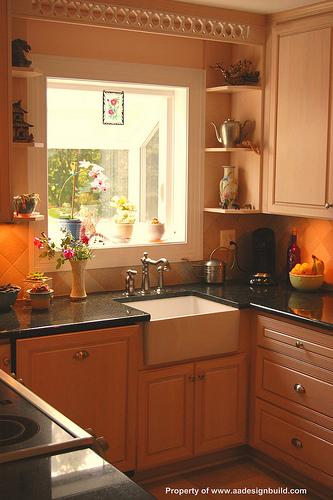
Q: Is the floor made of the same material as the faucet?
A: No, the floor is made of wood and the faucet is made of metal.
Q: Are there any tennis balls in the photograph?
A: No, there are no tennis balls.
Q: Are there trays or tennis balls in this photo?
A: No, there are no tennis balls or trays.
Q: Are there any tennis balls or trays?
A: No, there are no tennis balls or trays.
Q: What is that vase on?
A: The vase is on the shelf.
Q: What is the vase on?
A: The vase is on the shelf.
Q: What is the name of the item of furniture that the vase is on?
A: The piece of furniture is a shelf.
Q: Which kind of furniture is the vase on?
A: The vase is on the shelf.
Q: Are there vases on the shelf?
A: Yes, there is a vase on the shelf.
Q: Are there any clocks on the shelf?
A: No, there is a vase on the shelf.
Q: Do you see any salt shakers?
A: No, there are no salt shakers.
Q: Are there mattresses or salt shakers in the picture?
A: No, there are no salt shakers or mattresses.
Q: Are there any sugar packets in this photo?
A: No, there are no sugar packets.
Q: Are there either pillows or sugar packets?
A: No, there are no sugar packets or pillows.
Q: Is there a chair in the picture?
A: No, there are no chairs.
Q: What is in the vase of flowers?
A: The flowers are in the vase.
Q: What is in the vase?
A: The flowers are in the vase.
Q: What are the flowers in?
A: The flowers are in the vase.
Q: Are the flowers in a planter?
A: No, the flowers are in a vase.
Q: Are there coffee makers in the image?
A: Yes, there is a coffee maker.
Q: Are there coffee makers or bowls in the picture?
A: Yes, there is a coffee maker.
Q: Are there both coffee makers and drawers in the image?
A: Yes, there are both a coffee maker and a drawer.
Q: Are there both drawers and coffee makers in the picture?
A: Yes, there are both a coffee maker and a drawer.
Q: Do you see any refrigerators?
A: No, there are no refrigerators.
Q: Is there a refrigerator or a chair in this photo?
A: No, there are no refrigerators or chairs.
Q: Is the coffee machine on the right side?
A: Yes, the coffee machine is on the right of the image.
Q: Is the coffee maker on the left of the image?
A: No, the coffee maker is on the right of the image.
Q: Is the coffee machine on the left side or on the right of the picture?
A: The coffee machine is on the right of the image.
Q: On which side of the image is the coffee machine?
A: The coffee machine is on the right of the image.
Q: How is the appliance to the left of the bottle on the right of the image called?
A: The appliance is a coffee maker.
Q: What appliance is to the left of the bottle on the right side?
A: The appliance is a coffee maker.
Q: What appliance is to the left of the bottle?
A: The appliance is a coffee maker.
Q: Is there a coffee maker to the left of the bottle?
A: Yes, there is a coffee maker to the left of the bottle.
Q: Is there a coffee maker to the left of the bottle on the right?
A: Yes, there is a coffee maker to the left of the bottle.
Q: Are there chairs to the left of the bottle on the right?
A: No, there is a coffee maker to the left of the bottle.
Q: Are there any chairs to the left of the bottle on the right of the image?
A: No, there is a coffee maker to the left of the bottle.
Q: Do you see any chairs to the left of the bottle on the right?
A: No, there is a coffee maker to the left of the bottle.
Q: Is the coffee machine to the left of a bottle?
A: Yes, the coffee machine is to the left of a bottle.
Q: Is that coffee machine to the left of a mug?
A: No, the coffee machine is to the left of a bottle.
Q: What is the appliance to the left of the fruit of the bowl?
A: The appliance is a coffee maker.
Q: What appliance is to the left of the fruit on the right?
A: The appliance is a coffee maker.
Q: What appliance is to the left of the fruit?
A: The appliance is a coffee maker.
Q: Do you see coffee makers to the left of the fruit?
A: Yes, there is a coffee maker to the left of the fruit.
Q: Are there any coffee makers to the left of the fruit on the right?
A: Yes, there is a coffee maker to the left of the fruit.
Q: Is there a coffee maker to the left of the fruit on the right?
A: Yes, there is a coffee maker to the left of the fruit.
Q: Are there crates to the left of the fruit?
A: No, there is a coffee maker to the left of the fruit.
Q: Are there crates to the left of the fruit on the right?
A: No, there is a coffee maker to the left of the fruit.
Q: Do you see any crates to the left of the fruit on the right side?
A: No, there is a coffee maker to the left of the fruit.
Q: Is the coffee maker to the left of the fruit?
A: Yes, the coffee maker is to the left of the fruit.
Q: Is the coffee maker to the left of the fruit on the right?
A: Yes, the coffee maker is to the left of the fruit.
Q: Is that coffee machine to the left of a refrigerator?
A: No, the coffee machine is to the left of the fruit.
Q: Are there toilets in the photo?
A: No, there are no toilets.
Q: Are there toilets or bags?
A: No, there are no toilets or bags.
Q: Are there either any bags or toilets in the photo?
A: No, there are no toilets or bags.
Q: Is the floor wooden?
A: Yes, the floor is wooden.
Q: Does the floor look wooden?
A: Yes, the floor is wooden.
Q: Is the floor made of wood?
A: Yes, the floor is made of wood.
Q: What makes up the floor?
A: The floor is made of wood.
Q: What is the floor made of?
A: The floor is made of wood.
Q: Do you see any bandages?
A: No, there are no bandages.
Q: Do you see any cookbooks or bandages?
A: No, there are no bandages or cookbooks.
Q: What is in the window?
A: The orchid is in the window.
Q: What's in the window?
A: The orchid is in the window.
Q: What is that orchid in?
A: The orchid is in the window.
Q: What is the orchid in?
A: The orchid is in the window.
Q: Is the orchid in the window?
A: Yes, the orchid is in the window.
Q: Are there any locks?
A: No, there are no locks.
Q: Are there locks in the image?
A: No, there are no locks.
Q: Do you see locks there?
A: No, there are no locks.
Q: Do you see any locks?
A: No, there are no locks.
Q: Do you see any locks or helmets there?
A: No, there are no locks or helmets.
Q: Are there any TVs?
A: No, there are no tvs.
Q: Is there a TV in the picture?
A: No, there are no televisions.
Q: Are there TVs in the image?
A: No, there are no tvs.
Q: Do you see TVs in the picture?
A: No, there are no tvs.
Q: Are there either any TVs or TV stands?
A: No, there are no TVs or TV stands.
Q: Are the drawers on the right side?
A: Yes, the drawers are on the right of the image.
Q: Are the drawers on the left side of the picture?
A: No, the drawers are on the right of the image.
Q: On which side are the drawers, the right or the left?
A: The drawers are on the right of the image.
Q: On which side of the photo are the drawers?
A: The drawers are on the right of the image.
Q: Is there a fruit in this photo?
A: Yes, there is a fruit.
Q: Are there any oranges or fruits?
A: Yes, there is a fruit.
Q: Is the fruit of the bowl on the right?
A: Yes, the fruit is on the right of the image.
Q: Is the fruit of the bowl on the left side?
A: No, the fruit is on the right of the image.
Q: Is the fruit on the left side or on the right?
A: The fruit is on the right of the image.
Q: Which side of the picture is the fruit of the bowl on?
A: The fruit is on the right of the image.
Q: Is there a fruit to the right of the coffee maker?
A: Yes, there is a fruit to the right of the coffee maker.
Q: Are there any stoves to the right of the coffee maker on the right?
A: No, there is a fruit to the right of the coffee machine.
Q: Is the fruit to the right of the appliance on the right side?
A: Yes, the fruit is to the right of the coffee machine.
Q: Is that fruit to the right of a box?
A: No, the fruit is to the right of the coffee machine.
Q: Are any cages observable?
A: No, there are no cages.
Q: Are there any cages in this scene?
A: No, there are no cages.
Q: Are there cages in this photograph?
A: No, there are no cages.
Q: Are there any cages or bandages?
A: No, there are no cages or bandages.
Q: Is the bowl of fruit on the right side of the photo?
A: Yes, the bowl is on the right of the image.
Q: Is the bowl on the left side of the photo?
A: No, the bowl is on the right of the image.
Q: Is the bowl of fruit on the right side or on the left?
A: The bowl is on the right of the image.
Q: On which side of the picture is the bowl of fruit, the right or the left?
A: The bowl is on the right of the image.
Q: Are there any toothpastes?
A: No, there are no toothpastes.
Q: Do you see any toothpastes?
A: No, there are no toothpastes.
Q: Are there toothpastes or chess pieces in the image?
A: No, there are no toothpastes or chess pieces.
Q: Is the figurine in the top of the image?
A: Yes, the figurine is in the top of the image.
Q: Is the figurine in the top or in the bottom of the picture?
A: The figurine is in the top of the image.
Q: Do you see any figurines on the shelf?
A: Yes, there is a figurine on the shelf.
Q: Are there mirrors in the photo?
A: No, there are no mirrors.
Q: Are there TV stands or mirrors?
A: No, there are no mirrors or TV stands.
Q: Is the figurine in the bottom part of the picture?
A: No, the figurine is in the top of the image.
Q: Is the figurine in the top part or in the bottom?
A: The figurine is in the top of the image.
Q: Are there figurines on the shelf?
A: Yes, there is a figurine on the shelf.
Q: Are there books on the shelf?
A: No, there is a figurine on the shelf.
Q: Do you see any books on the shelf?
A: No, there is a figurine on the shelf.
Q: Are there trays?
A: No, there are no trays.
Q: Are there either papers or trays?
A: No, there are no trays or papers.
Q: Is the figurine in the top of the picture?
A: Yes, the figurine is in the top of the image.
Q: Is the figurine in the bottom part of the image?
A: No, the figurine is in the top of the image.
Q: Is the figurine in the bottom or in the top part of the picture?
A: The figurine is in the top of the image.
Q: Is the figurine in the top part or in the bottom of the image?
A: The figurine is in the top of the image.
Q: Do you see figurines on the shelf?
A: Yes, there is a figurine on the shelf.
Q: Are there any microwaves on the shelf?
A: No, there is a figurine on the shelf.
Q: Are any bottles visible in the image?
A: Yes, there is a bottle.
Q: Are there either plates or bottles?
A: Yes, there is a bottle.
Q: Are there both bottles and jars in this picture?
A: No, there is a bottle but no jars.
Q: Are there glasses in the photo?
A: No, there are no glasses.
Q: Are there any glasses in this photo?
A: No, there are no glasses.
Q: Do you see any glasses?
A: No, there are no glasses.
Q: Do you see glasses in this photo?
A: No, there are no glasses.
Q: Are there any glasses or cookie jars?
A: No, there are no glasses or cookie jars.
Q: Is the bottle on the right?
A: Yes, the bottle is on the right of the image.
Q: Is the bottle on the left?
A: No, the bottle is on the right of the image.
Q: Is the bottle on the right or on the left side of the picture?
A: The bottle is on the right of the image.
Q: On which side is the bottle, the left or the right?
A: The bottle is on the right of the image.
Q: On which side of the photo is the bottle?
A: The bottle is on the right of the image.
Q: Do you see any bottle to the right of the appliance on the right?
A: Yes, there is a bottle to the right of the coffee machine.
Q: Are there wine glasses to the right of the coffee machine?
A: No, there is a bottle to the right of the coffee machine.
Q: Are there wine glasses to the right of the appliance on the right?
A: No, there is a bottle to the right of the coffee machine.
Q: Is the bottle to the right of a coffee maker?
A: Yes, the bottle is to the right of a coffee maker.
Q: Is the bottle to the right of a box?
A: No, the bottle is to the right of a coffee maker.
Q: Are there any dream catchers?
A: No, there are no dream catchers.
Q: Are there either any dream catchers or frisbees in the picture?
A: No, there are no dream catchers or frisbees.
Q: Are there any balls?
A: No, there are no balls.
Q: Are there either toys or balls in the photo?
A: No, there are no balls or toys.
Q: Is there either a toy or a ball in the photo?
A: No, there are no balls or toys.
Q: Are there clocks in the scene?
A: No, there are no clocks.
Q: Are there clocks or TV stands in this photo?
A: No, there are no clocks or TV stands.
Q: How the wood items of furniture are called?
A: The pieces of furniture are cabinets.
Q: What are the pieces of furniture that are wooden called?
A: The pieces of furniture are cabinets.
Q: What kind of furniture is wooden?
A: The furniture is cabinets.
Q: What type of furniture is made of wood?
A: The furniture is cabinets.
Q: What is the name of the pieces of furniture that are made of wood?
A: The pieces of furniture are cabinets.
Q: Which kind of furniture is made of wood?
A: The furniture is cabinets.